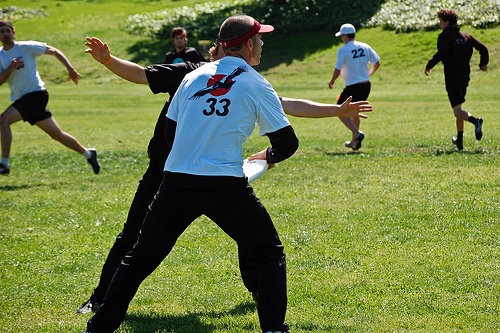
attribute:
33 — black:
[199, 92, 230, 120]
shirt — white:
[167, 56, 284, 179]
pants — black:
[130, 156, 286, 320]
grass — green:
[1, 1, 494, 327]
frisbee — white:
[235, 149, 274, 186]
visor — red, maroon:
[217, 21, 278, 45]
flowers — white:
[127, 9, 223, 30]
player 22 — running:
[323, 17, 380, 152]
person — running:
[5, 8, 83, 198]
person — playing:
[424, 1, 490, 153]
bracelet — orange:
[101, 48, 118, 67]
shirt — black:
[421, 27, 491, 79]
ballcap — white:
[328, 18, 356, 36]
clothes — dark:
[415, 26, 490, 112]